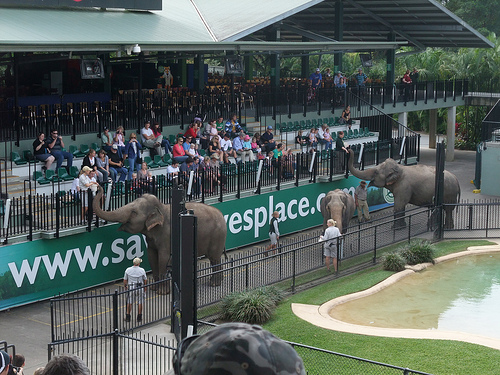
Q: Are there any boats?
A: No, there are no boats.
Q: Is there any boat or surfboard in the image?
A: No, there are no boats or surfboards.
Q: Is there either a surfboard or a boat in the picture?
A: No, there are no boats or surfboards.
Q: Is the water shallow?
A: Yes, the water is shallow.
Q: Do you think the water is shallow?
A: Yes, the water is shallow.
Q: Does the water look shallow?
A: Yes, the water is shallow.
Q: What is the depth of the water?
A: The water is shallow.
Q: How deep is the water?
A: The water is shallow.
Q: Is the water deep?
A: No, the water is shallow.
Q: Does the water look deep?
A: No, the water is shallow.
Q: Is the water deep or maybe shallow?
A: The water is shallow.